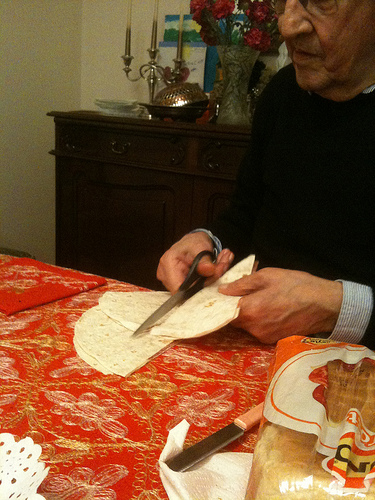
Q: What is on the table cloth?
A: The gold and red design.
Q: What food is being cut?
A: Tortillas.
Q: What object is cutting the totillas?
A: Scissors.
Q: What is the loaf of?
A: Bread.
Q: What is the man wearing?
A: A sweater.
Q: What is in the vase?
A: Red flowers.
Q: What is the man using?
A: Scissors.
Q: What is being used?
A: Scissors.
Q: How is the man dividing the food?
A: With scissors.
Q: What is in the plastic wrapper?
A: Bread.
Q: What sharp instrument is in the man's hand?
A: Scissors.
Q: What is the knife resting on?
A: A napkin.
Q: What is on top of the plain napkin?
A: A knife.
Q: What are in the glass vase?
A: Flowers.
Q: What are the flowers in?
A: A vase.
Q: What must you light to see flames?
A: Candles.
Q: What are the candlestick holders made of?
A: Brass.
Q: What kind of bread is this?
A: White bread.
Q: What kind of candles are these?
A: White and gold.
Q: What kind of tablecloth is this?
A: A red tablecloth.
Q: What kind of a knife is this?
A: A sharp knife.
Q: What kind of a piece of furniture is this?
A: A buffet.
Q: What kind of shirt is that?
A: Lines shirt.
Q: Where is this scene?
A: The dining room.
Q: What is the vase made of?
A: Glass.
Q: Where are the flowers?
A: On the cabinet.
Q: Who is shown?
A: A man.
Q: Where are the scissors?
A: In the man's hand.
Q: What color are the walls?
A: White.